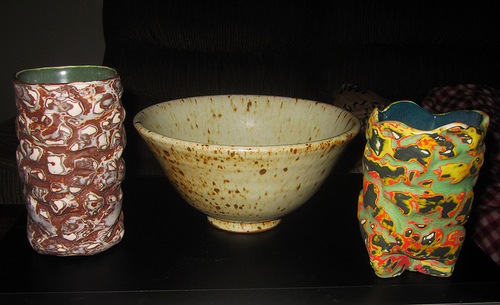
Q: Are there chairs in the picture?
A: Yes, there is a chair.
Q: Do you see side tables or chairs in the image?
A: Yes, there is a chair.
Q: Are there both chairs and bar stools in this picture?
A: No, there is a chair but no bar stools.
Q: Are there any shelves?
A: No, there are no shelves.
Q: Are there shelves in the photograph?
A: No, there are no shelves.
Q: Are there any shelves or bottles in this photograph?
A: No, there are no shelves or bottles.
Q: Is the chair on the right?
A: Yes, the chair is on the right of the image.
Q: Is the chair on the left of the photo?
A: No, the chair is on the right of the image.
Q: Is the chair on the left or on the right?
A: The chair is on the right of the image.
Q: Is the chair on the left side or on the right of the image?
A: The chair is on the right of the image.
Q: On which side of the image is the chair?
A: The chair is on the right of the image.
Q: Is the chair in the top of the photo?
A: Yes, the chair is in the top of the image.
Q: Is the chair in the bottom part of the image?
A: No, the chair is in the top of the image.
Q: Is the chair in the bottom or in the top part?
A: The chair is in the top of the image.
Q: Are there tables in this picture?
A: Yes, there is a table.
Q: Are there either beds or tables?
A: Yes, there is a table.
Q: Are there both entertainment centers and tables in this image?
A: No, there is a table but no entertainment centers.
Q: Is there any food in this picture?
A: No, there is no food.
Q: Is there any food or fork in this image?
A: No, there are no food or forks.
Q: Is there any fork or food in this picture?
A: No, there are no food or forks.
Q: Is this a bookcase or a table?
A: This is a table.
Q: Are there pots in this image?
A: Yes, there is a pot.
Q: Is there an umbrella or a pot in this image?
A: Yes, there is a pot.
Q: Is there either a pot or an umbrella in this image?
A: Yes, there is a pot.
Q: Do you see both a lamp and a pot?
A: No, there is a pot but no lamps.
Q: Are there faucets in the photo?
A: No, there are no faucets.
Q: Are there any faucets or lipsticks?
A: No, there are no faucets or lipsticks.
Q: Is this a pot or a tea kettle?
A: This is a pot.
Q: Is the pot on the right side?
A: Yes, the pot is on the right of the image.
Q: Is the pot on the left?
A: No, the pot is on the right of the image.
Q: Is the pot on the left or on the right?
A: The pot is on the right of the image.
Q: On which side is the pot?
A: The pot is on the right of the image.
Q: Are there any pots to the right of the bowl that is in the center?
A: Yes, there is a pot to the right of the bowl.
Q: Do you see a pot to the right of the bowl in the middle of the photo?
A: Yes, there is a pot to the right of the bowl.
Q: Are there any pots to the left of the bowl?
A: No, the pot is to the right of the bowl.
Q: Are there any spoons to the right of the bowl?
A: No, there is a pot to the right of the bowl.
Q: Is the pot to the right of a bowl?
A: Yes, the pot is to the right of a bowl.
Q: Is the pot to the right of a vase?
A: No, the pot is to the right of a bowl.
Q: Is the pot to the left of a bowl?
A: No, the pot is to the right of a bowl.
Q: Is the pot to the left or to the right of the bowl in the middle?
A: The pot is to the right of the bowl.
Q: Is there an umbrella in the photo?
A: No, there are no umbrellas.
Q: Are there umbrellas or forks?
A: No, there are no umbrellas or forks.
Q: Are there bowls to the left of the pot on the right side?
A: Yes, there is a bowl to the left of the pot.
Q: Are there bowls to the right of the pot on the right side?
A: No, the bowl is to the left of the pot.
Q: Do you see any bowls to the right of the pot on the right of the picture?
A: No, the bowl is to the left of the pot.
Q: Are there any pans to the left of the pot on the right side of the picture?
A: No, there is a bowl to the left of the pot.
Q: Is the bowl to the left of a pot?
A: Yes, the bowl is to the left of a pot.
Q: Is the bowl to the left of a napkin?
A: No, the bowl is to the left of a pot.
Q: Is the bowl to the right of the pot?
A: No, the bowl is to the left of the pot.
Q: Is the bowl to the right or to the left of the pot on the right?
A: The bowl is to the left of the pot.